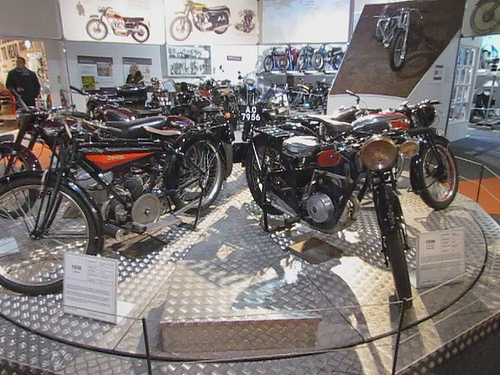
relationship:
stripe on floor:
[458, 155, 494, 187] [434, 132, 498, 216]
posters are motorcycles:
[55, 0, 261, 48] [86, 5, 233, 36]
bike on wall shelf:
[259, 44, 294, 72] [269, 62, 337, 82]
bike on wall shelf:
[287, 37, 326, 72] [269, 62, 337, 82]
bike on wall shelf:
[313, 43, 340, 74] [269, 62, 337, 82]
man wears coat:
[5, 57, 41, 111] [8, 72, 40, 99]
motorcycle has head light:
[232, 108, 417, 303] [358, 141, 394, 175]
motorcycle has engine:
[232, 108, 417, 303] [290, 182, 350, 234]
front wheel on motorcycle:
[381, 212, 417, 303] [250, 117, 415, 304]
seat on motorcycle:
[279, 125, 326, 164] [234, 113, 422, 318]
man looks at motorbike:
[5, 57, 41, 111] [0, 98, 225, 293]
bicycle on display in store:
[377, 3, 427, 72] [0, 0, 498, 374]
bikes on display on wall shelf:
[244, 113, 440, 308] [0, 157, 500, 370]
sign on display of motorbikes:
[60, 248, 120, 325] [2, 77, 460, 312]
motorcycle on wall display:
[171, 0, 230, 41] [164, 0, 261, 49]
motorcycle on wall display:
[87, 6, 151, 42] [55, 1, 165, 47]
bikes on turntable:
[6, 81, 460, 308] [0, 169, 498, 373]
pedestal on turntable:
[157, 249, 325, 357] [0, 169, 498, 373]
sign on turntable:
[51, 244, 136, 323] [0, 169, 498, 373]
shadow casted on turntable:
[200, 216, 254, 273] [0, 169, 498, 373]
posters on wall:
[55, 0, 261, 48] [0, 0, 392, 38]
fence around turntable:
[427, 55, 497, 136] [0, 169, 498, 373]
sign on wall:
[74, 51, 116, 94] [287, 11, 414, 52]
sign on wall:
[120, 56, 153, 91] [287, 11, 414, 52]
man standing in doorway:
[5, 53, 42, 130] [6, 34, 47, 110]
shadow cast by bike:
[164, 197, 390, 373] [226, 93, 444, 304]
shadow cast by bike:
[406, 201, 496, 346] [286, 96, 458, 212]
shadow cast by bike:
[110, 207, 211, 281] [0, 100, 233, 293]